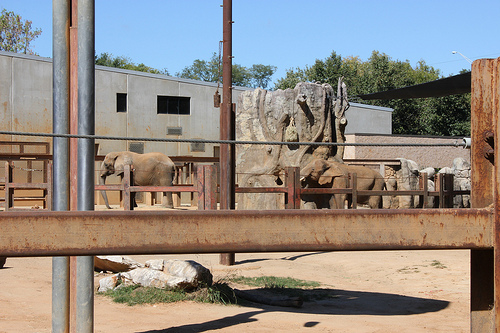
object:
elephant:
[300, 158, 389, 209]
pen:
[469, 57, 499, 333]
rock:
[233, 75, 350, 212]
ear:
[318, 163, 346, 185]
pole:
[0, 207, 497, 258]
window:
[157, 95, 191, 116]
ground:
[0, 202, 473, 331]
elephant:
[98, 151, 177, 209]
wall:
[0, 53, 225, 201]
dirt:
[0, 204, 472, 331]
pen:
[0, 183, 469, 195]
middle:
[153, 0, 312, 333]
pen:
[0, 206, 500, 258]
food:
[242, 143, 300, 201]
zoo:
[0, 0, 500, 333]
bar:
[0, 206, 494, 257]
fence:
[0, 56, 500, 332]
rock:
[98, 258, 213, 295]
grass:
[94, 280, 240, 307]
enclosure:
[0, 130, 473, 333]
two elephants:
[97, 150, 387, 209]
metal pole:
[51, 0, 94, 333]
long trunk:
[98, 168, 113, 209]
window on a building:
[116, 92, 127, 112]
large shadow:
[136, 260, 451, 333]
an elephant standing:
[98, 151, 179, 209]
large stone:
[97, 258, 212, 294]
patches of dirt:
[346, 256, 409, 320]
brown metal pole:
[219, 0, 236, 267]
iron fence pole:
[214, 0, 235, 264]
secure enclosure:
[0, 126, 499, 274]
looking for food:
[97, 132, 398, 227]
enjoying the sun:
[96, 150, 389, 209]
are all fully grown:
[297, 158, 388, 210]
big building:
[0, 50, 393, 207]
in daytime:
[0, 0, 500, 333]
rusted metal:
[0, 207, 491, 258]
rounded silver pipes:
[0, 130, 465, 147]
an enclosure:
[0, 0, 500, 333]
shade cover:
[356, 71, 471, 101]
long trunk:
[299, 163, 313, 182]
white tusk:
[299, 177, 305, 182]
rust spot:
[168, 241, 271, 254]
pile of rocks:
[378, 155, 471, 210]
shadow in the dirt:
[211, 284, 451, 315]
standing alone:
[98, 150, 178, 210]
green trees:
[274, 48, 473, 135]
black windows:
[156, 94, 191, 115]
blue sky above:
[0, 1, 500, 88]